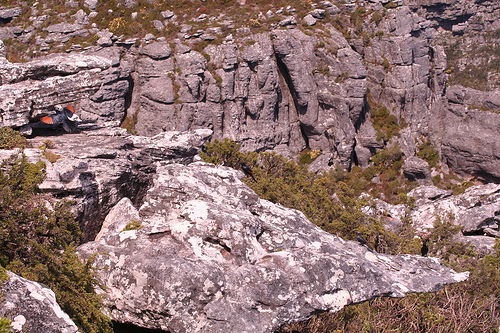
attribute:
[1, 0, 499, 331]
rock — Attractive 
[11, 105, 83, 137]
bear — black 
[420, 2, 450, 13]
shadows — Dark 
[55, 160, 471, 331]
rock — big 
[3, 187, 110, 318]
grass — bright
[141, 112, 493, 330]
plants — dry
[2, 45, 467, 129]
rock — large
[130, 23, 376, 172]
rock — big 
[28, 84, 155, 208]
bird — orange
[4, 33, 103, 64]
shrub — green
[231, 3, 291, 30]
shrub — green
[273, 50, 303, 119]
shadow — dark, deep